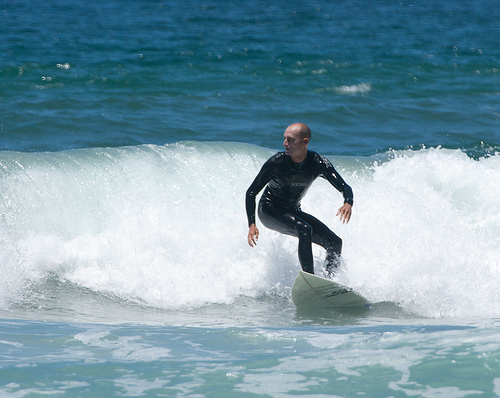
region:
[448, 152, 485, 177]
top of the wave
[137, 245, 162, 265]
bottom of the wave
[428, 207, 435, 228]
part of the wave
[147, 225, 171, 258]
part of an ocean wave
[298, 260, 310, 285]
tip of a board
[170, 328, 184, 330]
part of the ocean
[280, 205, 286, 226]
part of a swim suite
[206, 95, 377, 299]
a man surfing in the water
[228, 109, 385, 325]
a man wearing a black wet suit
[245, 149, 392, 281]
a shiny wetsuit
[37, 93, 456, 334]
a large foamy wave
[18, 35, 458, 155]
clear blue ripply water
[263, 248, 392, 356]
a large white surfboard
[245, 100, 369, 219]
a man with very short hair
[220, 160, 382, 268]
a man with bare hands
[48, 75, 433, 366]
a man surfing on a wave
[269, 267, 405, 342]
white surfboard floating on a wave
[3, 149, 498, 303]
wave breaking in ocean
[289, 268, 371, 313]
white long surf board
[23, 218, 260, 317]
white foam in ocean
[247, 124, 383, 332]
man surfing in ocean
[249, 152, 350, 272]
black rubber wet suit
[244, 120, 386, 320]
mam looking at shoreline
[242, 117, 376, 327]
man waiting for waves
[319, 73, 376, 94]
white cap in ocean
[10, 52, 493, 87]
wave forming in ocean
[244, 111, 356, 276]
man wearing wet suit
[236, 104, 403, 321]
this is a person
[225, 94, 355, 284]
the man is wearing a swimsuit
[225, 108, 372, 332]
the man is surfing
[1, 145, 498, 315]
this is a big wave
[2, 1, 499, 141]
the water is blue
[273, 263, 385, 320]
the surf board is white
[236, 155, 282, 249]
the hand of a man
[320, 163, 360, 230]
the hand of a man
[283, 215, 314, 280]
the leg of a man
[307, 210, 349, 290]
the leg of a man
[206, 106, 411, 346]
a man surfing in the ocean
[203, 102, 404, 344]
a man on a surfboard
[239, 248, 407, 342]
a white surfboard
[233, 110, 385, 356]
a man wearing a wet suit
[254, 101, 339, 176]
a balding man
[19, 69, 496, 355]
a wave breaking in the ocean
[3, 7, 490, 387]
dark blue ocean water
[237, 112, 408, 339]
a man standing while surfing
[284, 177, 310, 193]
wet suit that says xcel on it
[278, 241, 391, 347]
the tip of a surf board